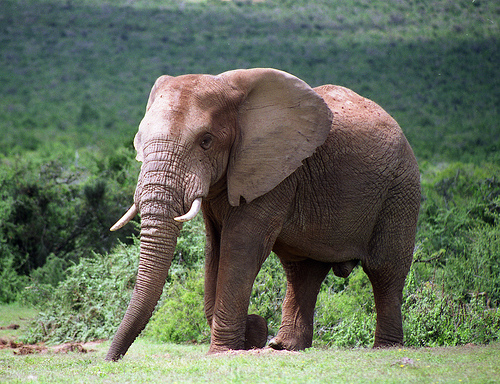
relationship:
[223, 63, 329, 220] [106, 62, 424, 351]
ear attached to elephant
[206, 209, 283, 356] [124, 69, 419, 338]
leg attached to elephant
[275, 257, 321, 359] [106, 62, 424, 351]
leg attached to elephant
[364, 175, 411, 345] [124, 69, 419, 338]
leg attached to elephant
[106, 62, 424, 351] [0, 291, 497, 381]
elephant walking in field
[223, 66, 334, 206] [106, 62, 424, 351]
ear of elephant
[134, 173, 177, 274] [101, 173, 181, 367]
wrinkles in elephant trunk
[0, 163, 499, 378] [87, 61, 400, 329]
grass behind elephant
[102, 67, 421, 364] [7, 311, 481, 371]
elephant walking through grass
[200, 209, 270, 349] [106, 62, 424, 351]
leg belonging to elephant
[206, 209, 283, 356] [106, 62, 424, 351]
leg belonging to elephant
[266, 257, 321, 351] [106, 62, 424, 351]
leg belonging to elephant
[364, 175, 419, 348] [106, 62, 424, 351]
leg belonging to elephant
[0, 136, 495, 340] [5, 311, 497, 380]
trees bordering field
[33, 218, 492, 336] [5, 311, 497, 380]
brush bordering field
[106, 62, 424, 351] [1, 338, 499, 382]
elephant standing on grass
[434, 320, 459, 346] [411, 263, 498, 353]
leaf on stem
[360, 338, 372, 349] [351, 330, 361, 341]
leaf on stem